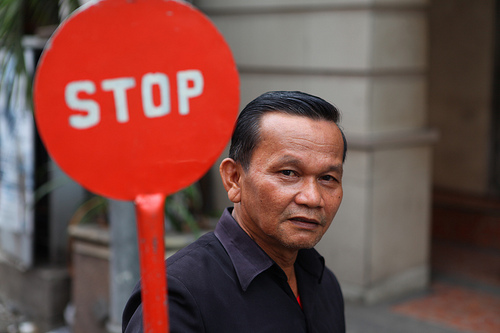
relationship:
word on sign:
[61, 68, 203, 128] [35, 0, 242, 331]